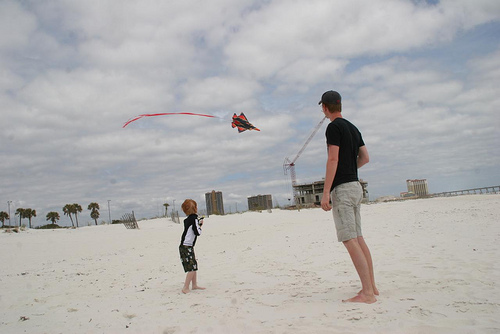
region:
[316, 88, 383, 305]
man with tan shorts, black shirt and a black hat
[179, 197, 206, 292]
boy with black and white shirt holding a kite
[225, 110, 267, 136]
black and orange kite shaped like a jet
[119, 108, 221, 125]
orange tail of a flying kite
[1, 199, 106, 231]
green palm trees on the beach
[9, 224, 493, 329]
light tan sandy beach at the ocean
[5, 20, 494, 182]
blue and white clouded sky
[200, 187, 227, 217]
tall building at the beach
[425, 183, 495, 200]
pier jutting into the ocean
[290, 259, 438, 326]
footprints in light tan sandy beach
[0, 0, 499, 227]
a cloudy sky above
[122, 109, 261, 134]
a red and black kite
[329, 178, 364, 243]
a pair of grey shorts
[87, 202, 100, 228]
palm tree in distance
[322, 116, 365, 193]
a black tee shirt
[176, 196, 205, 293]
a young child on beach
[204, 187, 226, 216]
a tall building in distance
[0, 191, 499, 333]
a soft sandy beach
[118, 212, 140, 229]
a leaning fence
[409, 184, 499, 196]
a bridge in distance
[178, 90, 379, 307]
a man and a boy flying a kite on the beach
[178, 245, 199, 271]
a boy wearing shorts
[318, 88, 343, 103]
man wearing a black cap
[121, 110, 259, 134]
a red and black kite flying in the sky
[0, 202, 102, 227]
palm trees in the distance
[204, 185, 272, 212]
buildings next to the beach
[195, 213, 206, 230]
a boy holding the strings of a kite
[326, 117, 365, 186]
man wearing a black T-shirt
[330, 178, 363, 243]
man wearing tan shorts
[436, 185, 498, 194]
a pier next to the beach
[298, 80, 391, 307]
Man wearing a black shirt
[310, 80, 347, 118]
Black cap on man's head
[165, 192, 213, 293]
Boy standing in sand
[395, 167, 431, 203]
Building in the background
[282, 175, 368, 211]
Building in the background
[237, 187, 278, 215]
Building in the background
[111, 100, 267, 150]
Kite in the sky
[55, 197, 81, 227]
Palm trees in the background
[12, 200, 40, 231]
Palm trees in the background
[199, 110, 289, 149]
Kite in the sky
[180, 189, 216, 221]
Hair on a boy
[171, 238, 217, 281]
Shorts on a boy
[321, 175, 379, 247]
Shorts on a man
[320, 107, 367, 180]
Black shirt on a man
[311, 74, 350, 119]
Black hat on a man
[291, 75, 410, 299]
Man standing in sand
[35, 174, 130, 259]
Palm trees by a beach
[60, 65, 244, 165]
White clouds in a blue sky